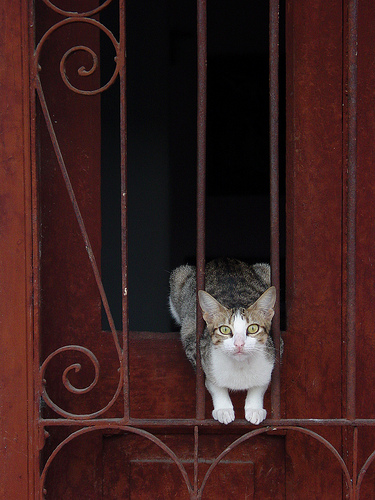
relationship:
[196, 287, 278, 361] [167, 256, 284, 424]
head of cat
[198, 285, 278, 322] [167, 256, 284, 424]
ears of cat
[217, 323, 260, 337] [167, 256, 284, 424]
eyes of cat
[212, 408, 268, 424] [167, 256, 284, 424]
paws of cat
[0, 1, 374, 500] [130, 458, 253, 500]
door missing panel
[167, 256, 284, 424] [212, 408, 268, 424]
cat has paws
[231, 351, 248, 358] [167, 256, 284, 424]
mouth of cat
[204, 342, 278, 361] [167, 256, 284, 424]
whiskers of cat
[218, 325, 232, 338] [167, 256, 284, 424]
eyes of cat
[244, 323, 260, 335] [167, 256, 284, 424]
left eye of cat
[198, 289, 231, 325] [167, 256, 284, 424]
ears of cat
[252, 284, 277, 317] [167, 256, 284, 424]
left ear of cat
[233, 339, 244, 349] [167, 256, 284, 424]
nose of cat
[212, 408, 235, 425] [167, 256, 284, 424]
paws of cat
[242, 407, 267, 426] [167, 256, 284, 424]
left paw of cat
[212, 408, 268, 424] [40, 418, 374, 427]
paws on rail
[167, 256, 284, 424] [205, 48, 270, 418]
cat laying through opening